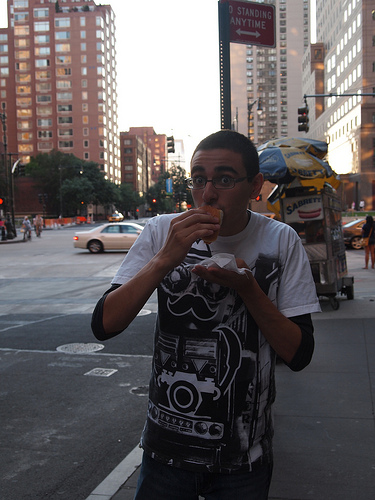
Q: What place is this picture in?
A: It is at the sidewalk.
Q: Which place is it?
A: It is a sidewalk.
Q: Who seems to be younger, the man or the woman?
A: The man is younger than the woman.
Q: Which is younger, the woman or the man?
A: The man is younger than the woman.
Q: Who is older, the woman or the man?
A: The woman is older than the man.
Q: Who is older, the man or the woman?
A: The woman is older than the man.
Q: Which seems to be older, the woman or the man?
A: The woman is older than the man.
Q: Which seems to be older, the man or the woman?
A: The woman is older than the man.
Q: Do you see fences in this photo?
A: No, there are no fences.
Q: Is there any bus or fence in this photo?
A: No, there are no fences or buses.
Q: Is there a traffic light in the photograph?
A: Yes, there is a traffic light.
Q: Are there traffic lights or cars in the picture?
A: Yes, there is a traffic light.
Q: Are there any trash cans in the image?
A: No, there are no trash cans.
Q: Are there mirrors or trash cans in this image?
A: No, there are no trash cans or mirrors.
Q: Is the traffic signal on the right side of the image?
A: Yes, the traffic signal is on the right of the image.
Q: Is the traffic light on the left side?
A: No, the traffic light is on the right of the image.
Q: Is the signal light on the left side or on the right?
A: The signal light is on the right of the image.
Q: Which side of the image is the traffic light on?
A: The traffic light is on the right of the image.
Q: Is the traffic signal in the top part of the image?
A: Yes, the traffic signal is in the top of the image.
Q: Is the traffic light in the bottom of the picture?
A: No, the traffic light is in the top of the image.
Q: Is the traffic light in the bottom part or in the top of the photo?
A: The traffic light is in the top of the image.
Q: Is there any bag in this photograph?
A: No, there are no bags.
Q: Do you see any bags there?
A: No, there are no bags.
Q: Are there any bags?
A: No, there are no bags.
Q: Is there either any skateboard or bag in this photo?
A: No, there are no bags or skateboards.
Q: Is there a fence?
A: No, there are no fences.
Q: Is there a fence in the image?
A: No, there are no fences.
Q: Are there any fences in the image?
A: No, there are no fences.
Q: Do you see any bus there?
A: No, there are no buses.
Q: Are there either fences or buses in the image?
A: No, there are no buses or fences.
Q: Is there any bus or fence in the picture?
A: No, there are no buses or fences.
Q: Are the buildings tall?
A: Yes, the buildings are tall.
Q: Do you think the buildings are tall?
A: Yes, the buildings are tall.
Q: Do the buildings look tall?
A: Yes, the buildings are tall.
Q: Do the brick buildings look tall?
A: Yes, the buildings are tall.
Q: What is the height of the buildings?
A: The buildings are tall.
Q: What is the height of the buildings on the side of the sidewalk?
A: The buildings are tall.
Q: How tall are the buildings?
A: The buildings are tall.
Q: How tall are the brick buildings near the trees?
A: The buildings are tall.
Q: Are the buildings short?
A: No, the buildings are tall.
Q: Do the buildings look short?
A: No, the buildings are tall.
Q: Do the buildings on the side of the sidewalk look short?
A: No, the buildings are tall.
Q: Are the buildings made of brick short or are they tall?
A: The buildings are tall.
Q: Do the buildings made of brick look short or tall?
A: The buildings are tall.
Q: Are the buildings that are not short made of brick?
A: Yes, the buildings are made of brick.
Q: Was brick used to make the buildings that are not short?
A: Yes, the buildings are made of brick.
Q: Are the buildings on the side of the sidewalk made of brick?
A: Yes, the buildings are made of brick.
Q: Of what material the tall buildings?
A: The buildings are made of brick.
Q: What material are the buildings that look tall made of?
A: The buildings are made of brick.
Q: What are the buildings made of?
A: The buildings are made of brick.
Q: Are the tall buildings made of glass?
A: No, the buildings are made of brick.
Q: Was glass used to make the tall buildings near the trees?
A: No, the buildings are made of brick.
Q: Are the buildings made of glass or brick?
A: The buildings are made of brick.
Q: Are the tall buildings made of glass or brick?
A: The buildings are made of brick.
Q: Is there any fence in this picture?
A: No, there are no fences.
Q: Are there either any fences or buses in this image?
A: No, there are no fences or buses.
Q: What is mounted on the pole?
A: The sign is mounted on the pole.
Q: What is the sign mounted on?
A: The sign is mounted on the pole.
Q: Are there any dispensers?
A: No, there are no dispensers.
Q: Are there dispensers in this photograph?
A: No, there are no dispensers.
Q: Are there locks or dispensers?
A: No, there are no dispensers or locks.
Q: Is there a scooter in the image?
A: No, there are no scooters.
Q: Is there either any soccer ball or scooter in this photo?
A: No, there are no scooters or soccer balls.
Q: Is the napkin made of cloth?
A: No, the napkin is made of paper.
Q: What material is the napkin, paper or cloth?
A: The napkin is made of paper.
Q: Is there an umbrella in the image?
A: Yes, there are umbrellas.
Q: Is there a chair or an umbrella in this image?
A: Yes, there are umbrellas.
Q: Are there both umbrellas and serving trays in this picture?
A: No, there are umbrellas but no serving trays.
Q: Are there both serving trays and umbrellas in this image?
A: No, there are umbrellas but no serving trays.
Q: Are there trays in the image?
A: No, there are no trays.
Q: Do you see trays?
A: No, there are no trays.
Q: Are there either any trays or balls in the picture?
A: No, there are no trays or balls.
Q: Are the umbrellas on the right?
A: Yes, the umbrellas are on the right of the image.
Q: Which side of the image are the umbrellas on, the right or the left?
A: The umbrellas are on the right of the image.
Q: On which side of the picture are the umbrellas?
A: The umbrellas are on the right of the image.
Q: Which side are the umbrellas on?
A: The umbrellas are on the right of the image.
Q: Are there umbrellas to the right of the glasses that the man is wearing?
A: Yes, there are umbrellas to the right of the glasses.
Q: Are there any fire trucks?
A: No, there are no fire trucks.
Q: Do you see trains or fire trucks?
A: No, there are no fire trucks or trains.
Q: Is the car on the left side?
A: Yes, the car is on the left of the image.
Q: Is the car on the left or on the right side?
A: The car is on the left of the image.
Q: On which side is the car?
A: The car is on the left of the image.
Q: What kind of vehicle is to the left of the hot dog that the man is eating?
A: The vehicle is a car.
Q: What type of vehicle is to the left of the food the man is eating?
A: The vehicle is a car.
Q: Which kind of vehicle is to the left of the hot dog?
A: The vehicle is a car.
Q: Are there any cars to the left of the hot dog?
A: Yes, there is a car to the left of the hot dog.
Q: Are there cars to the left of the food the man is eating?
A: Yes, there is a car to the left of the hot dog.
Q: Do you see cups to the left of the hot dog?
A: No, there is a car to the left of the hot dog.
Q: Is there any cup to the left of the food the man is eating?
A: No, there is a car to the left of the hot dog.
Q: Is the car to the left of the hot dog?
A: Yes, the car is to the left of the hot dog.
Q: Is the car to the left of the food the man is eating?
A: Yes, the car is to the left of the hot dog.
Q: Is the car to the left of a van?
A: No, the car is to the left of the hot dog.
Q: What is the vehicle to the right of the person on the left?
A: The vehicle is a car.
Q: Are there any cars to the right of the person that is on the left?
A: Yes, there is a car to the right of the person.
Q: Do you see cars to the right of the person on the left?
A: Yes, there is a car to the right of the person.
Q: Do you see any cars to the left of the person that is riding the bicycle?
A: No, the car is to the right of the person.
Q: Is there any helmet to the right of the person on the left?
A: No, there is a car to the right of the person.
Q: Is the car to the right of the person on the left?
A: Yes, the car is to the right of the person.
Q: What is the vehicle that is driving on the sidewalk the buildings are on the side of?
A: The vehicle is a car.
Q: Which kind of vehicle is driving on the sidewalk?
A: The vehicle is a car.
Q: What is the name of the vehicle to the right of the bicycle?
A: The vehicle is a car.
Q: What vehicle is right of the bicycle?
A: The vehicle is a car.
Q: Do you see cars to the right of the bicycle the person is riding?
A: Yes, there is a car to the right of the bicycle.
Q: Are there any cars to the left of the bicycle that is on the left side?
A: No, the car is to the right of the bicycle.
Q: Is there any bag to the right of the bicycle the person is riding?
A: No, there is a car to the right of the bicycle.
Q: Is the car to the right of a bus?
A: No, the car is to the right of a bicycle.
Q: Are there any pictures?
A: No, there are no pictures.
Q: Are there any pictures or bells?
A: No, there are no pictures or bells.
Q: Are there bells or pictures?
A: No, there are no pictures or bells.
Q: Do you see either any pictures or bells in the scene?
A: No, there are no pictures or bells.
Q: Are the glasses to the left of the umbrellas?
A: Yes, the glasses are to the left of the umbrellas.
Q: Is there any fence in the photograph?
A: No, there are no fences.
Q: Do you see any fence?
A: No, there are no fences.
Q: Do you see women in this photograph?
A: Yes, there is a woman.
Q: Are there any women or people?
A: Yes, there is a woman.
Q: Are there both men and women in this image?
A: Yes, there are both a woman and a man.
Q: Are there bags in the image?
A: No, there are no bags.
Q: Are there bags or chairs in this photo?
A: No, there are no bags or chairs.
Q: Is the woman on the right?
A: Yes, the woman is on the right of the image.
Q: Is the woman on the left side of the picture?
A: No, the woman is on the right of the image.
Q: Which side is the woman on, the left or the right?
A: The woman is on the right of the image.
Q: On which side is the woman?
A: The woman is on the right of the image.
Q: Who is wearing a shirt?
A: The woman is wearing a shirt.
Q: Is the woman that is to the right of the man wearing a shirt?
A: Yes, the woman is wearing a shirt.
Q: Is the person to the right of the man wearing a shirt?
A: Yes, the woman is wearing a shirt.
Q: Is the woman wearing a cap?
A: No, the woman is wearing a shirt.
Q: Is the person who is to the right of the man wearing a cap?
A: No, the woman is wearing a shirt.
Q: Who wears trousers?
A: The woman wears trousers.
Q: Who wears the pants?
A: The woman wears trousers.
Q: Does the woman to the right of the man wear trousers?
A: Yes, the woman wears trousers.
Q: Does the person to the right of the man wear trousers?
A: Yes, the woman wears trousers.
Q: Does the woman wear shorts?
A: No, the woman wears trousers.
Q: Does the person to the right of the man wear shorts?
A: No, the woman wears trousers.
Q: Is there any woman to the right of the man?
A: Yes, there is a woman to the right of the man.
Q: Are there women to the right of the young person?
A: Yes, there is a woman to the right of the man.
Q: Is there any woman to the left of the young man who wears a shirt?
A: No, the woman is to the right of the man.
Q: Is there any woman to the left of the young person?
A: No, the woman is to the right of the man.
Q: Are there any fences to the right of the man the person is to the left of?
A: No, there is a woman to the right of the man.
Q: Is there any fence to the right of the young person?
A: No, there is a woman to the right of the man.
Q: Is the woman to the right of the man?
A: Yes, the woman is to the right of the man.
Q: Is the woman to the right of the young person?
A: Yes, the woman is to the right of the man.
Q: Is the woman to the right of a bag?
A: No, the woman is to the right of the man.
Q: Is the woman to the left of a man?
A: No, the woman is to the right of a man.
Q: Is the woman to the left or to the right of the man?
A: The woman is to the right of the man.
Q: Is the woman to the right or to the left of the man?
A: The woman is to the right of the man.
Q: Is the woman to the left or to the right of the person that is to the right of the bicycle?
A: The woman is to the right of the man.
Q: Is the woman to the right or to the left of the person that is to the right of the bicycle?
A: The woman is to the right of the man.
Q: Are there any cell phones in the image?
A: No, there are no cell phones.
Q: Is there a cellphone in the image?
A: No, there are no cell phones.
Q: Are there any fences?
A: No, there are no fences.